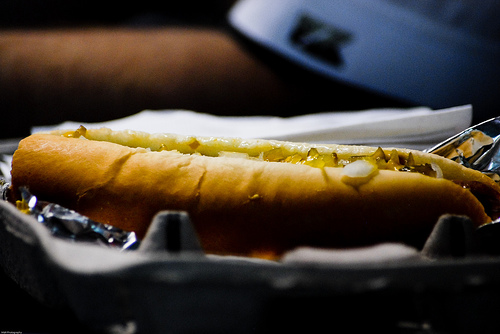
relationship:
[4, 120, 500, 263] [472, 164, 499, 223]
bun has tip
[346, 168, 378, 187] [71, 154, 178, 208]
onions on top of bun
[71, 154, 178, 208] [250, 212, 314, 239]
bun has shadwo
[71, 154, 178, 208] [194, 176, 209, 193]
bun has wrinkles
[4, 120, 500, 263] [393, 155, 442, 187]
bun has relish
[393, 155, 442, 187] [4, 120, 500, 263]
relish on bun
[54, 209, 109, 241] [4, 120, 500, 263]
foil beneath bun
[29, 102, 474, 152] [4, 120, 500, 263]
napkin under bun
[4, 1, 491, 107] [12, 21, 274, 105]
man has arm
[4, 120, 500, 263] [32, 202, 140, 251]
bun has foil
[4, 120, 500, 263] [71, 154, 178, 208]
bun has bun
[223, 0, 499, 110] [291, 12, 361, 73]
shirt has logo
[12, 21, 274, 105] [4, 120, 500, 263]
arm behind bun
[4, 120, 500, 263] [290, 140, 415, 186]
bun has garnish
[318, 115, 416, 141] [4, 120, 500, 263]
napkin behind bun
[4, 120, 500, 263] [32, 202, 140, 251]
bun under foil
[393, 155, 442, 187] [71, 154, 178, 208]
relish inside bun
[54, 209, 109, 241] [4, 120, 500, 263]
foil surrounds bun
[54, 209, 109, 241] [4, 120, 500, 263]
foil under bun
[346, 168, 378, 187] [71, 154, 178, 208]
onions on bun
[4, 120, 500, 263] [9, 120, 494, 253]
bun on bun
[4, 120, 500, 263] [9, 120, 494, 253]
bun in bun